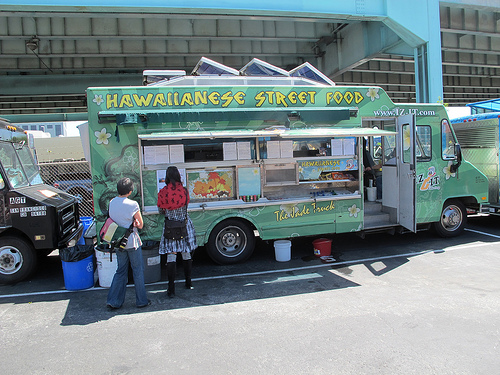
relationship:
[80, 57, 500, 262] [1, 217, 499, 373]
food truck parked on street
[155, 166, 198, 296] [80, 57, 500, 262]
woman in front of food truck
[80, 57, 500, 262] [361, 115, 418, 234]
food truck has door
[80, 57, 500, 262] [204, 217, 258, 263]
food truck has rear wheel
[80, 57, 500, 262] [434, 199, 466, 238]
food truck has front wheel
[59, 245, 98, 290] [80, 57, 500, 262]
garbage can next to food truck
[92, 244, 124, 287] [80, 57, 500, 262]
garbage can next to food truck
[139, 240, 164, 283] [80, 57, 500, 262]
garbage can next to food truck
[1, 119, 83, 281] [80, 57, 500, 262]
truck parked behind food truck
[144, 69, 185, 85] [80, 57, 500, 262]
solar panel on top of food truck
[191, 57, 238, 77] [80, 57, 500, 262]
solar panel on top of food truck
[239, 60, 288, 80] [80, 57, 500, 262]
solar panel on top of food truck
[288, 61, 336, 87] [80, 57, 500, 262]
solar panel on top of food truck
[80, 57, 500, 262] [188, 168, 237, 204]
food truck has service window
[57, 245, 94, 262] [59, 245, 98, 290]
trash bag inside garbage can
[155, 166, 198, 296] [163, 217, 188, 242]
woman carrying bag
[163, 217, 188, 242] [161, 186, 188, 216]
bag around back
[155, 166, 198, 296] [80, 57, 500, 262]
woman next to food truck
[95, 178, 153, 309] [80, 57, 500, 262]
woman next to food truck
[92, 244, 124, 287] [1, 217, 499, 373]
garbage can on top of street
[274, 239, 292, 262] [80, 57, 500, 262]
bucket under food truck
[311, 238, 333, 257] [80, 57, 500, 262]
bucket under food truck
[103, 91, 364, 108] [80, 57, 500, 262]
text printed on food truck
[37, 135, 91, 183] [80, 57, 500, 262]
building behind food truck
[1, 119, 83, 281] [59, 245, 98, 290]
truck behind garbage can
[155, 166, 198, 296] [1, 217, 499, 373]
woman standing on street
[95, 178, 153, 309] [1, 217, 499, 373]
woman standing on street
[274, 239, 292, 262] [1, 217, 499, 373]
bucket on top of street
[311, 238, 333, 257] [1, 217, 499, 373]
bucket on top of street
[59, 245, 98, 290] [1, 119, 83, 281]
garbage can in front of truck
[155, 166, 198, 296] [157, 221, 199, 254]
woman wearing skirt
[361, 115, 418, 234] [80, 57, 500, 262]
door to food truck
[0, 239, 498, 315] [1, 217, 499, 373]
stripe painted on street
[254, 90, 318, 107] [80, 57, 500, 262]
street written on food truck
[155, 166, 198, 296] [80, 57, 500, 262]
woman buying from food truck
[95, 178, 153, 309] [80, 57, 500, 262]
woman buying from food truck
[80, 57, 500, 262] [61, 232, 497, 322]
food truck casts shadow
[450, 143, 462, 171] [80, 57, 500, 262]
side mirror attached to food truck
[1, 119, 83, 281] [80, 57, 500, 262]
truck behind food truck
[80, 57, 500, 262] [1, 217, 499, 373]
food truck on top of street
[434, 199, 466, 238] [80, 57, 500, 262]
front wheel under food truck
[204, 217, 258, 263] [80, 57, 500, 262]
rear wheel under food truck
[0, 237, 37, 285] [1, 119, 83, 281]
tire under truck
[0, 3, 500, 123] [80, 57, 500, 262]
bridge behind food truck